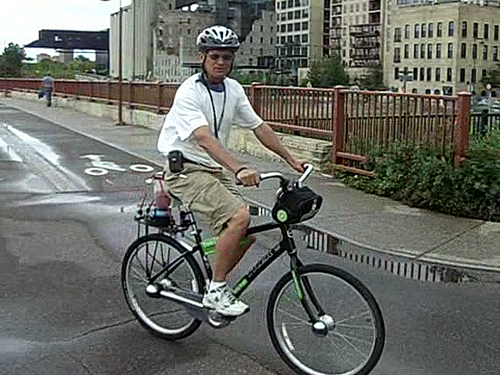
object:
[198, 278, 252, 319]
sneaker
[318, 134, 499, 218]
bushes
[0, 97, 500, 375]
ground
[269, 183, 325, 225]
bag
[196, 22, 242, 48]
helmet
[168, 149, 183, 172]
cell phone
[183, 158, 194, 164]
belt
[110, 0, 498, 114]
buildings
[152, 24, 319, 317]
man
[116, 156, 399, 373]
bicycle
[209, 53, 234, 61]
glasses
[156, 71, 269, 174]
shirt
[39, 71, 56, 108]
man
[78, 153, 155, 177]
markings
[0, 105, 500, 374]
street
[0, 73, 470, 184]
fence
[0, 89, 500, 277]
sidewalk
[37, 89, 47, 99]
bag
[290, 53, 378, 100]
background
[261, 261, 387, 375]
tire